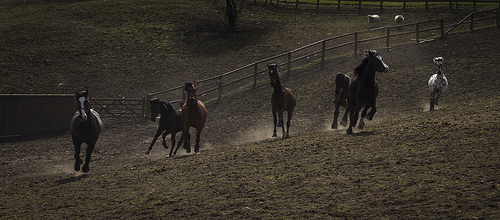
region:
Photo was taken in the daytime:
[7, 6, 497, 215]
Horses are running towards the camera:
[43, 34, 476, 183]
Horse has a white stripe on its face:
[68, 83, 95, 130]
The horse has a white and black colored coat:
[413, 53, 460, 121]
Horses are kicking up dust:
[230, 108, 358, 148]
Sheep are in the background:
[346, 8, 418, 39]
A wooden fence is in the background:
[98, 14, 468, 117]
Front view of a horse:
[45, 83, 122, 186]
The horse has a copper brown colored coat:
[168, 75, 223, 165]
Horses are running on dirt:
[48, 116, 445, 191]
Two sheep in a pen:
[363, 12, 405, 24]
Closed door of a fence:
[88, 93, 148, 120]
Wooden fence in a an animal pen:
[208, 69, 261, 96]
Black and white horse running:
[423, 56, 450, 111]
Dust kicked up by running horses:
[146, 120, 369, 152]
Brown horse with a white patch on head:
[73, 91, 93, 119]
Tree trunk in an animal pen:
[216, 0, 247, 46]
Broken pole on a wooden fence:
[438, 13, 475, 35]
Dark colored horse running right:
[343, 46, 392, 141]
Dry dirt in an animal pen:
[241, 160, 471, 216]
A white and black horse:
[425, 55, 448, 111]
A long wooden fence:
[144, 4, 499, 119]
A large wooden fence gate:
[88, 93, 149, 123]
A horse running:
[65, 88, 105, 174]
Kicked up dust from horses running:
[43, 100, 443, 180]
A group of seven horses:
[68, 47, 456, 174]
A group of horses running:
[63, 47, 452, 174]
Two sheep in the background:
[363, 9, 407, 32]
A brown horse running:
[265, 61, 299, 141]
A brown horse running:
[177, 80, 209, 156]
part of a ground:
[256, 146, 300, 192]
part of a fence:
[206, 55, 239, 105]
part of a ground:
[271, 131, 307, 171]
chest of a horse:
[422, 65, 453, 94]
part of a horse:
[433, 10, 446, 103]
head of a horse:
[71, 113, 87, 136]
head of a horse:
[180, 82, 202, 105]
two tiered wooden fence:
[192, 6, 474, 107]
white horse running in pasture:
[381, 57, 459, 108]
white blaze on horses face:
[64, 90, 97, 122]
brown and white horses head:
[262, 60, 282, 94]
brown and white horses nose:
[369, 60, 399, 77]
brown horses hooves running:
[229, 115, 304, 164]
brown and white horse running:
[57, 77, 109, 188]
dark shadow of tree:
[132, 9, 284, 71]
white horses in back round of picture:
[340, 5, 413, 30]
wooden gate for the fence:
[73, 87, 160, 137]